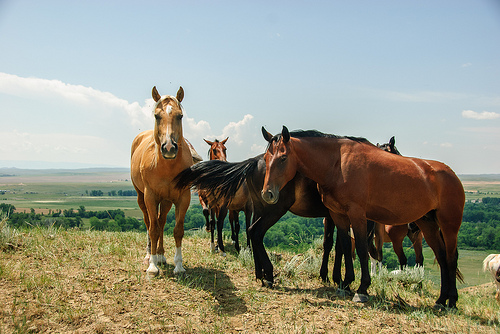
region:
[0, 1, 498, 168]
a light blue sky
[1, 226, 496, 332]
trampled grass around horse's feet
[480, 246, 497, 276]
a white horse tail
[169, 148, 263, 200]
a black horse tail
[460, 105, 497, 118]
a white cloud in the sky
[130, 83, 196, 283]
a light brown horse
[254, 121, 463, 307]
a brown horse with a black mane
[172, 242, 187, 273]
a white sock on a horse's leg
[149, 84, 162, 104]
the ear of a horse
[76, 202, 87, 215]
a tree in the distance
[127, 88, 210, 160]
the head of a horse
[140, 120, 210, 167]
the mouth of a horse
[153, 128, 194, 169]
the nose of a horse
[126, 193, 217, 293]
the legs of a horse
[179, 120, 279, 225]
the tail of a horse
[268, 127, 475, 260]
the body of a horse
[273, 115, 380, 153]
the main of a horse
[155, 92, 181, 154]
A large horses face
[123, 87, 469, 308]
A group of horses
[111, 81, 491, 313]
A group of horses in field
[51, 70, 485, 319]
A small group of horses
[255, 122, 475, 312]
A large brown horse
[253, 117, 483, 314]
A large adult horse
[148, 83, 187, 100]
A horses pointed ears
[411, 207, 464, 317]
A horses back legs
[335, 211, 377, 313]
A horses front legs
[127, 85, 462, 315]
Group of horses standing on a hill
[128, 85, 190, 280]
Tan horse standing on a hill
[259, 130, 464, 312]
Brown horse standing on a hill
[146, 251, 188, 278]
White lower front legs on horse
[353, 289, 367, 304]
Gray hoof on horse's leg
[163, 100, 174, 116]
White mark on horse's head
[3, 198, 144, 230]
Green trees in valley below horses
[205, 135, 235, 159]
Ears laid sideways on horse's head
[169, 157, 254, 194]
Swishing black tail on horse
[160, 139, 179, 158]
Flared nostrils on horse's nose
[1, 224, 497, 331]
trampled grass under horses' feet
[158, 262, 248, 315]
the shadow of a horse on the ground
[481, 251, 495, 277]
a white horse tail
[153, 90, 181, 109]
a blond forelock on a horse's head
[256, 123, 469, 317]
a brown horse with a black mane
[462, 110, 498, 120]
a small white cloud in the sky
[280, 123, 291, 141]
a black ear on a horse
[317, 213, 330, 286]
long leg on the brown horse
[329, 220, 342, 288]
long leg on the brown horse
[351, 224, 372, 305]
long leg on the brown horse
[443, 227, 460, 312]
long leg on the brown horse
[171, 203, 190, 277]
long leg on the brown horse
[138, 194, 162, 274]
long leg on the brown horse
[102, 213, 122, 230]
green leaves on the tree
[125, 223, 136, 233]
green leaves on the tree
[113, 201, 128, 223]
green leaves on the tree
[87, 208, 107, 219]
green leaves on the tree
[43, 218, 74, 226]
green leaves on the tree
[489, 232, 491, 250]
green leaves on the tree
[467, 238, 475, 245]
green leaves on the tree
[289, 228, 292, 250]
green leaves on the tree